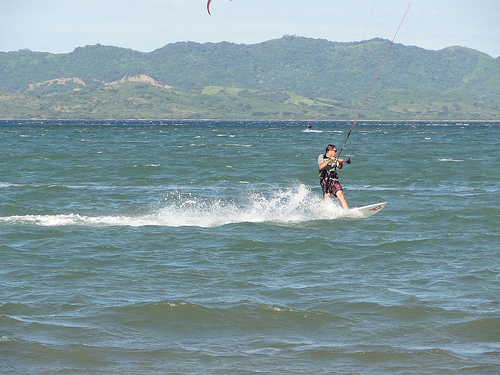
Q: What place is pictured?
A: It is an ocean.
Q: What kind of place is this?
A: It is an ocean.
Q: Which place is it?
A: It is an ocean.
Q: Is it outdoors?
A: Yes, it is outdoors.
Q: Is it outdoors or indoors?
A: It is outdoors.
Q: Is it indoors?
A: No, it is outdoors.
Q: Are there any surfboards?
A: Yes, there is a surfboard.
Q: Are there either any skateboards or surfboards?
A: Yes, there is a surfboard.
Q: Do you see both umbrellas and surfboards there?
A: No, there is a surfboard but no umbrellas.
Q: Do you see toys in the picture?
A: No, there are no toys.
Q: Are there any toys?
A: No, there are no toys.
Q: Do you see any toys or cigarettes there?
A: No, there are no toys or cigarettes.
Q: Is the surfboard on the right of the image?
A: Yes, the surfboard is on the right of the image.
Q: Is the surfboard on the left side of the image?
A: No, the surfboard is on the right of the image.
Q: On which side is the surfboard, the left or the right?
A: The surfboard is on the right of the image.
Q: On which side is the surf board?
A: The surf board is on the right of the image.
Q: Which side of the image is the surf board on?
A: The surf board is on the right of the image.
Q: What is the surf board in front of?
A: The surf board is in front of the water.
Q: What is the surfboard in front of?
A: The surf board is in front of the water.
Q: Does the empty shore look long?
A: Yes, the shore is long.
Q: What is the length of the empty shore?
A: The shore is long.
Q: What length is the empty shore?
A: The shore is long.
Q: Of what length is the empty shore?
A: The shore is long.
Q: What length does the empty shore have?
A: The shore has long length.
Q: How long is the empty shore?
A: The sea shore is long.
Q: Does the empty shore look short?
A: No, the shore is long.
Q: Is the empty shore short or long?
A: The shore is long.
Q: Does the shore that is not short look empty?
A: Yes, the shore is empty.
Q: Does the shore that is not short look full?
A: No, the shore is empty.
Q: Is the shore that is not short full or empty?
A: The shore is empty.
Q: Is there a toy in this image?
A: No, there are no toys.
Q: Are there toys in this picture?
A: No, there are no toys.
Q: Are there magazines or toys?
A: No, there are no toys or magazines.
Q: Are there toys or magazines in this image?
A: No, there are no toys or magazines.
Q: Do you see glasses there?
A: No, there are no glasses.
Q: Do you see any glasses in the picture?
A: No, there are no glasses.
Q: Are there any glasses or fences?
A: No, there are no glasses or fences.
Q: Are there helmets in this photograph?
A: No, there are no helmets.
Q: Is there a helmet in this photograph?
A: No, there are no helmets.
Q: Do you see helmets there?
A: No, there are no helmets.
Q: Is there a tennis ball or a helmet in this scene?
A: No, there are no helmets or tennis balls.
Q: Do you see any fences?
A: No, there are no fences.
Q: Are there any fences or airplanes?
A: No, there are no fences or airplanes.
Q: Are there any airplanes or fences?
A: No, there are no fences or airplanes.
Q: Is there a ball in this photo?
A: No, there are no balls.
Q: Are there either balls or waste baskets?
A: No, there are no balls or waste baskets.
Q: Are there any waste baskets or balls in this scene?
A: No, there are no balls or waste baskets.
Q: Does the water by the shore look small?
A: Yes, the water is small.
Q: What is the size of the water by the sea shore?
A: The water is small.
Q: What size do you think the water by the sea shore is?
A: The water is small.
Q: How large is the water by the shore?
A: The water is small.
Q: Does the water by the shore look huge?
A: No, the water is small.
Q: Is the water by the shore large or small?
A: The water is small.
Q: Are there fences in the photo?
A: No, there are no fences.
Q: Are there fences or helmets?
A: No, there are no fences or helmets.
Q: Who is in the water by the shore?
A: The man is in the water.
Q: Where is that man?
A: The man is in the water.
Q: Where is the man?
A: The man is in the water.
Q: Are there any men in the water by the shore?
A: Yes, there is a man in the water.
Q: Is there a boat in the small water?
A: No, there is a man in the water.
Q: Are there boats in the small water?
A: No, there is a man in the water.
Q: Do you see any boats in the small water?
A: No, there is a man in the water.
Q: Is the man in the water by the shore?
A: Yes, the man is in the water.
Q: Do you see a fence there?
A: No, there are no fences.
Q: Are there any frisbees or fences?
A: No, there are no fences or frisbees.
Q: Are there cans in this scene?
A: No, there are no cans.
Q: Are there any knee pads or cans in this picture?
A: No, there are no cans or knee pads.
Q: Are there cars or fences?
A: No, there are no fences or cars.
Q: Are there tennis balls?
A: No, there are no tennis balls.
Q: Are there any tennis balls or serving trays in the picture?
A: No, there are no tennis balls or serving trays.